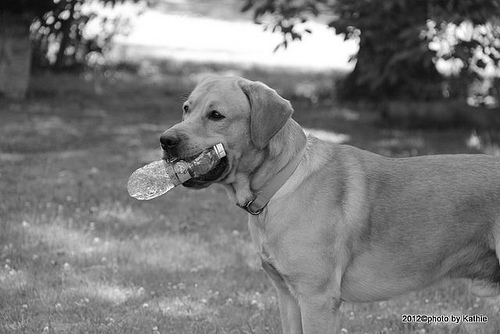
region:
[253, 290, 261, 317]
white mark is spotted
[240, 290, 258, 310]
white mark is spotted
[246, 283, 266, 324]
white mark is spotted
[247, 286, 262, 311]
white mark is spotted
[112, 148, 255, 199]
plactic water bottle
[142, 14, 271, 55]
sunshine on a road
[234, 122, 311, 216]
a collar on a dog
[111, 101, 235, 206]
a dog carring a bottle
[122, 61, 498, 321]
a yellow lab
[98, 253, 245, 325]
long grass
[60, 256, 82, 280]
small white flowers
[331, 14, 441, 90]
a tree trunck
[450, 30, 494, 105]
low hanging branches with leaves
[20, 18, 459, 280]
a summer time photo in the park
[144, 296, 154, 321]
white mark is spotted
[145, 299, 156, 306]
white mark is spotted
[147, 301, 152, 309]
white mark is spotted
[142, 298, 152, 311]
white mark is spotted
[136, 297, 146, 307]
white mark is spotted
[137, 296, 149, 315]
white mark is spotted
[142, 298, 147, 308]
white mark is spotted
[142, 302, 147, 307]
white mark is spotted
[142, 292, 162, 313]
white mark is spotted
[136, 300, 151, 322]
white mark is spotted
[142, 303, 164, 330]
white mark is spotted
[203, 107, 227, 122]
the eye of the dog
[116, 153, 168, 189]
a water bottle in dogs mouth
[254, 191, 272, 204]
the dogs collar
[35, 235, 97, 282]
grass under the dog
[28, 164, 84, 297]
the grass is below the dog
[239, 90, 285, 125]
the ear of the dog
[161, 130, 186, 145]
the nose of the dog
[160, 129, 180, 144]
the snout of the dog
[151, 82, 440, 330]
a dog with a water bottle in its mouth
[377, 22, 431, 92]
a tree in the background